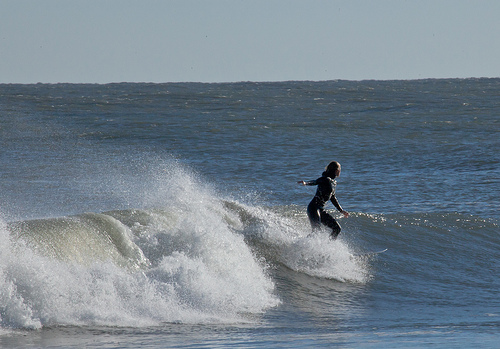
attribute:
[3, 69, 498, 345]
water — ocean